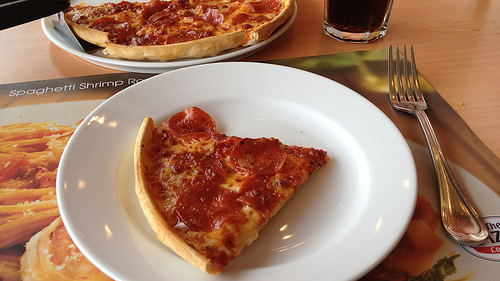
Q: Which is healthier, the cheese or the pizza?
A: The cheese is healthier than the pizza.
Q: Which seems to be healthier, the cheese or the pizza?
A: The cheese is healthier than the pizza.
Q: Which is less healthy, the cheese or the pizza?
A: The pizza is less healthy than the cheese.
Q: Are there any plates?
A: Yes, there is a plate.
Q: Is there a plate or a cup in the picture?
A: Yes, there is a plate.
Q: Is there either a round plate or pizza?
A: Yes, there is a round plate.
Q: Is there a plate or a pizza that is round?
A: Yes, the plate is round.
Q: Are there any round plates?
A: Yes, there is a round plate.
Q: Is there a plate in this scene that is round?
A: Yes, there is a plate that is round.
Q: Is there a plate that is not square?
A: Yes, there is a round plate.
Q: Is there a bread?
A: No, there is no breads.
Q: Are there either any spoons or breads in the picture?
A: No, there are no breads or spoons.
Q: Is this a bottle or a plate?
A: This is a plate.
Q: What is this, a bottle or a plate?
A: This is a plate.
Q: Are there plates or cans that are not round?
A: No, there is a plate but it is round.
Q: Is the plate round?
A: Yes, the plate is round.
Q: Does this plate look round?
A: Yes, the plate is round.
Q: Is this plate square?
A: No, the plate is round.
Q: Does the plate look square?
A: No, the plate is round.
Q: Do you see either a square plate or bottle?
A: No, there is a plate but it is round.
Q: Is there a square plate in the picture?
A: No, there is a plate but it is round.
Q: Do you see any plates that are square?
A: No, there is a plate but it is round.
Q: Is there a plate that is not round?
A: No, there is a plate but it is round.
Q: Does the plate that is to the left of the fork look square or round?
A: The plate is round.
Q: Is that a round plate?
A: Yes, that is a round plate.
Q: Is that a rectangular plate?
A: No, that is a round plate.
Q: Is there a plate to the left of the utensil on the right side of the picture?
A: Yes, there is a plate to the left of the fork.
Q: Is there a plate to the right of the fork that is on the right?
A: No, the plate is to the left of the fork.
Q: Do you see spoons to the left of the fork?
A: No, there is a plate to the left of the fork.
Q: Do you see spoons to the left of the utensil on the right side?
A: No, there is a plate to the left of the fork.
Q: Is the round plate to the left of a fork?
A: Yes, the plate is to the left of a fork.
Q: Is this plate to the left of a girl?
A: No, the plate is to the left of a fork.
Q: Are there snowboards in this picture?
A: No, there are no snowboards.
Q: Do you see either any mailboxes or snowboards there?
A: No, there are no snowboards or mailboxes.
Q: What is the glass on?
A: The glass is on the table.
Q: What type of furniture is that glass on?
A: The glass is on the table.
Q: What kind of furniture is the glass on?
A: The glass is on the table.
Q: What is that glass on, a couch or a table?
A: The glass is on a table.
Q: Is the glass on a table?
A: Yes, the glass is on a table.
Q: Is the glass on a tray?
A: No, the glass is on a table.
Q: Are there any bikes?
A: No, there are no bikes.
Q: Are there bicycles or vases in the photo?
A: No, there are no bicycles or vases.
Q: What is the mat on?
A: The mat is on the table.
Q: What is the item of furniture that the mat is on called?
A: The piece of furniture is a table.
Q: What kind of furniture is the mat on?
A: The mat is on the table.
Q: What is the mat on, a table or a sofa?
A: The mat is on a table.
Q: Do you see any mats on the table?
A: Yes, there is a mat on the table.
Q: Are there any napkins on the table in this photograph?
A: No, there is a mat on the table.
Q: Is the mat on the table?
A: Yes, the mat is on the table.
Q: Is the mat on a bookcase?
A: No, the mat is on the table.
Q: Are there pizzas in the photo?
A: Yes, there is a pizza.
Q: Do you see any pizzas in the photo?
A: Yes, there is a pizza.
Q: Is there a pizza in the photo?
A: Yes, there is a pizza.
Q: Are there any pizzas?
A: Yes, there is a pizza.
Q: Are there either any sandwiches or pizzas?
A: Yes, there is a pizza.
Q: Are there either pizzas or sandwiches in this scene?
A: Yes, there is a pizza.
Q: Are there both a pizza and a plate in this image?
A: Yes, there are both a pizza and a plate.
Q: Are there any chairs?
A: No, there are no chairs.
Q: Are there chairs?
A: No, there are no chairs.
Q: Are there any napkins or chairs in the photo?
A: No, there are no chairs or napkins.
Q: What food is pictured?
A: The food is a pizza.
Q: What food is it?
A: The food is a pizza.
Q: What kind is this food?
A: That is a pizza.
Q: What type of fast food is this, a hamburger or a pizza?
A: That is a pizza.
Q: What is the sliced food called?
A: The food is a pizza.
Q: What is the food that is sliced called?
A: The food is a pizza.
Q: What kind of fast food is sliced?
A: The fast food is a pizza.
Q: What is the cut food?
A: The food is a pizza.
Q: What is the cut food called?
A: The food is a pizza.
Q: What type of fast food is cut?
A: The fast food is a pizza.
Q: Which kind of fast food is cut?
A: The fast food is a pizza.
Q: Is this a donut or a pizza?
A: This is a pizza.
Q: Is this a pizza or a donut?
A: This is a pizza.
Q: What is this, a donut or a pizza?
A: This is a pizza.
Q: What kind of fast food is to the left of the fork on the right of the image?
A: The food is a pizza.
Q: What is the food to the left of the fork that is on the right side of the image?
A: The food is a pizza.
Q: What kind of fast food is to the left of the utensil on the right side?
A: The food is a pizza.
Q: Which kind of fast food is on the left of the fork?
A: The food is a pizza.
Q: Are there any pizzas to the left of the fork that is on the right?
A: Yes, there is a pizza to the left of the fork.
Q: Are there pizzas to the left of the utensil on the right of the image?
A: Yes, there is a pizza to the left of the fork.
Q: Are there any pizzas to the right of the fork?
A: No, the pizza is to the left of the fork.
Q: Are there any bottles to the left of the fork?
A: No, there is a pizza to the left of the fork.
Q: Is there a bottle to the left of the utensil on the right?
A: No, there is a pizza to the left of the fork.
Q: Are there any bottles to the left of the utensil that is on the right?
A: No, there is a pizza to the left of the fork.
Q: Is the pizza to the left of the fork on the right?
A: Yes, the pizza is to the left of the fork.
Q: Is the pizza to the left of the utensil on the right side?
A: Yes, the pizza is to the left of the fork.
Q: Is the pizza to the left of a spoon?
A: No, the pizza is to the left of the fork.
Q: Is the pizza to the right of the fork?
A: No, the pizza is to the left of the fork.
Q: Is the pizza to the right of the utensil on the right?
A: No, the pizza is to the left of the fork.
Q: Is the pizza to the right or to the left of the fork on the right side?
A: The pizza is to the left of the fork.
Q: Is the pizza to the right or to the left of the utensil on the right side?
A: The pizza is to the left of the fork.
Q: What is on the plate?
A: The pizza is on the plate.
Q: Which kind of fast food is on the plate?
A: The food is a pizza.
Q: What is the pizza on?
A: The pizza is on the plate.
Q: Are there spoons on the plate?
A: No, there is a pizza on the plate.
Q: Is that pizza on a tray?
A: No, the pizza is on the plate.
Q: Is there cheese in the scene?
A: Yes, there is cheese.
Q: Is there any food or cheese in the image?
A: Yes, there is cheese.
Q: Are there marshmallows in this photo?
A: No, there are no marshmallows.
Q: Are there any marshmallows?
A: No, there are no marshmallows.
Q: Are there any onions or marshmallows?
A: No, there are no marshmallows or onions.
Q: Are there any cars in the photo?
A: No, there are no cars.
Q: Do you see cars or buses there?
A: No, there are no cars or buses.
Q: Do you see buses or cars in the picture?
A: No, there are no cars or buses.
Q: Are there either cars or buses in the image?
A: No, there are no cars or buses.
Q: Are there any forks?
A: Yes, there is a fork.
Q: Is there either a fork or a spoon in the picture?
A: Yes, there is a fork.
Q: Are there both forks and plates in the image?
A: Yes, there are both a fork and a plate.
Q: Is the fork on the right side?
A: Yes, the fork is on the right of the image.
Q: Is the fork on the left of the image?
A: No, the fork is on the right of the image.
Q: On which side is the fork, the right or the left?
A: The fork is on the right of the image.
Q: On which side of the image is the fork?
A: The fork is on the right of the image.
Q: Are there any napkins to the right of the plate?
A: No, there is a fork to the right of the plate.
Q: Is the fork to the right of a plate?
A: Yes, the fork is to the right of a plate.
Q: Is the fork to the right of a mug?
A: No, the fork is to the right of a plate.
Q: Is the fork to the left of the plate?
A: No, the fork is to the right of the plate.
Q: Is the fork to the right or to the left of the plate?
A: The fork is to the right of the plate.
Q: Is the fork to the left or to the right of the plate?
A: The fork is to the right of the plate.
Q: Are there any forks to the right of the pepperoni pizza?
A: Yes, there is a fork to the right of the pizza.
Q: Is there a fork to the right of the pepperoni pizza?
A: Yes, there is a fork to the right of the pizza.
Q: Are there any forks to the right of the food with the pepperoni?
A: Yes, there is a fork to the right of the pizza.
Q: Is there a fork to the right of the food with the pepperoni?
A: Yes, there is a fork to the right of the pizza.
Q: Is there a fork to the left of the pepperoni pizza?
A: No, the fork is to the right of the pizza.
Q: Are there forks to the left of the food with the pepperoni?
A: No, the fork is to the right of the pizza.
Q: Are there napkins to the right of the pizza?
A: No, there is a fork to the right of the pizza.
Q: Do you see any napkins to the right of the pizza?
A: No, there is a fork to the right of the pizza.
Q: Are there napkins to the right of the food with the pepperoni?
A: No, there is a fork to the right of the pizza.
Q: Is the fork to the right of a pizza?
A: Yes, the fork is to the right of a pizza.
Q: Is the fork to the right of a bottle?
A: No, the fork is to the right of a pizza.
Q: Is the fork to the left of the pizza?
A: No, the fork is to the right of the pizza.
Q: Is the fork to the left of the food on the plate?
A: No, the fork is to the right of the pizza.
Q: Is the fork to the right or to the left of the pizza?
A: The fork is to the right of the pizza.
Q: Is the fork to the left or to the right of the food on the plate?
A: The fork is to the right of the pizza.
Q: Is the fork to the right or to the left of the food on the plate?
A: The fork is to the right of the pizza.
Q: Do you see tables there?
A: Yes, there is a table.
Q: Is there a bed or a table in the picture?
A: Yes, there is a table.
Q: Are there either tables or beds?
A: Yes, there is a table.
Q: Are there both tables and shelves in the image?
A: No, there is a table but no shelves.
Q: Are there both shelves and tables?
A: No, there is a table but no shelves.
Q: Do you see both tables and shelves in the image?
A: No, there is a table but no shelves.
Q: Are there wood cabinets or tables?
A: Yes, there is a wood table.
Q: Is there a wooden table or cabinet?
A: Yes, there is a wood table.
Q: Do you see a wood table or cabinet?
A: Yes, there is a wood table.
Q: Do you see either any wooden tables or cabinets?
A: Yes, there is a wood table.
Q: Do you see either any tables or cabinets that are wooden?
A: Yes, the table is wooden.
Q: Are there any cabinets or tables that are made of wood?
A: Yes, the table is made of wood.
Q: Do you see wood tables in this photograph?
A: Yes, there is a wood table.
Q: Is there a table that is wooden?
A: Yes, there is a table that is wooden.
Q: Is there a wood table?
A: Yes, there is a table that is made of wood.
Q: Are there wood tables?
A: Yes, there is a table that is made of wood.